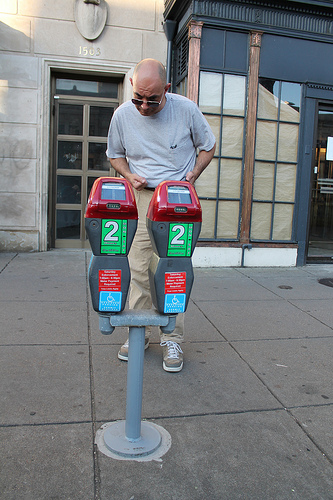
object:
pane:
[55, 206, 81, 248]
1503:
[79, 46, 100, 57]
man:
[105, 58, 215, 372]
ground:
[0, 246, 333, 500]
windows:
[250, 77, 304, 242]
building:
[0, 0, 331, 272]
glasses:
[131, 88, 166, 107]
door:
[51, 73, 123, 250]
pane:
[55, 100, 85, 139]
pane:
[88, 104, 115, 141]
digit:
[171, 225, 185, 245]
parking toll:
[84, 177, 138, 316]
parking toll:
[146, 180, 202, 313]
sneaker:
[160, 332, 185, 372]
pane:
[57, 135, 83, 170]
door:
[305, 100, 333, 265]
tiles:
[192, 299, 333, 338]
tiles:
[89, 342, 285, 420]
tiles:
[0, 298, 88, 346]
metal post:
[125, 326, 145, 441]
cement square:
[2, 263, 87, 304]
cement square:
[0, 343, 91, 423]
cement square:
[93, 411, 332, 500]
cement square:
[192, 267, 281, 301]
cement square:
[231, 335, 332, 412]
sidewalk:
[1, 252, 331, 499]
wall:
[1, 0, 173, 256]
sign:
[164, 293, 186, 313]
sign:
[99, 291, 123, 312]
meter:
[145, 180, 202, 334]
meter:
[83, 176, 138, 335]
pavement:
[3, 249, 332, 498]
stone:
[193, 296, 331, 342]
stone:
[0, 299, 88, 345]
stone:
[193, 275, 281, 301]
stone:
[1, 246, 86, 299]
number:
[96, 47, 101, 56]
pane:
[86, 139, 112, 174]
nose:
[141, 98, 149, 110]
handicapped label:
[164, 293, 186, 313]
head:
[129, 58, 171, 116]